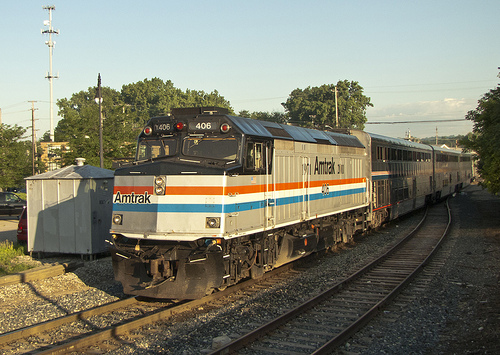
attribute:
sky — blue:
[0, 0, 498, 144]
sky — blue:
[94, 0, 438, 87]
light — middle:
[151, 176, 167, 191]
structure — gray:
[18, 158, 109, 258]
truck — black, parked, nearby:
[0, 190, 25, 214]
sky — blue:
[191, 11, 351, 89]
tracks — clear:
[277, 285, 397, 354]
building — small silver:
[22, 160, 115, 256]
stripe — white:
[200, 186, 366, 208]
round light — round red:
[141, 122, 155, 139]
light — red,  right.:
[211, 118, 243, 144]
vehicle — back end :
[15, 207, 33, 240]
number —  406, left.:
[192, 119, 214, 131]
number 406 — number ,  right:
[192, 119, 212, 132]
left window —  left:
[140, 139, 178, 160]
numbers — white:
[193, 120, 213, 130]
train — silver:
[108, 99, 493, 304]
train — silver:
[69, 105, 499, 306]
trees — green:
[73, 85, 362, 135]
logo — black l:
[312, 157, 335, 175]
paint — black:
[231, 131, 279, 184]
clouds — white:
[426, 100, 465, 112]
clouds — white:
[369, 100, 417, 120]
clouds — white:
[290, 42, 348, 62]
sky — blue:
[3, 0, 498, 78]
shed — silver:
[22, 156, 107, 260]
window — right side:
[241, 136, 271, 186]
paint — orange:
[184, 186, 230, 196]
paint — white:
[195, 193, 218, 205]